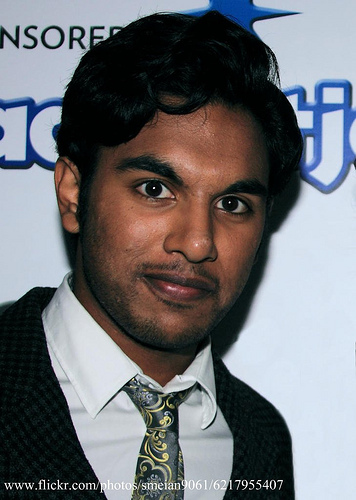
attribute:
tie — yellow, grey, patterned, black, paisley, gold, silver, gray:
[122, 377, 199, 500]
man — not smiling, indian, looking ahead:
[0, 10, 305, 499]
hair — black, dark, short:
[54, 11, 302, 227]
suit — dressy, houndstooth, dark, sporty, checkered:
[0, 288, 293, 500]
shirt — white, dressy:
[42, 271, 234, 499]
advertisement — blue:
[0, 1, 355, 197]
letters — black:
[0, 24, 124, 51]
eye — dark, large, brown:
[133, 179, 176, 201]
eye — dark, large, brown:
[214, 196, 251, 213]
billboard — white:
[1, 1, 355, 499]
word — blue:
[2, 79, 355, 195]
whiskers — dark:
[80, 204, 246, 350]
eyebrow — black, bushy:
[114, 151, 185, 185]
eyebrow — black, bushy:
[222, 178, 271, 199]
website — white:
[3, 479, 284, 495]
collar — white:
[41, 272, 220, 432]